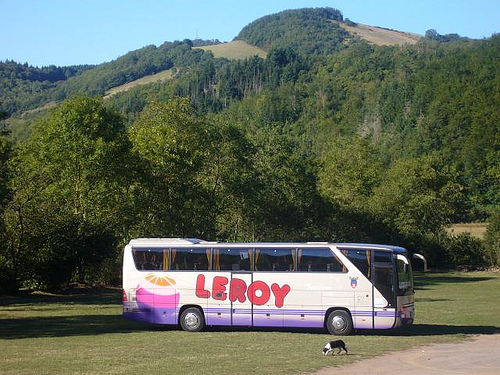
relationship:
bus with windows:
[122, 237, 427, 336] [296, 248, 348, 272]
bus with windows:
[122, 237, 427, 336] [252, 247, 296, 271]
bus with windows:
[122, 237, 427, 336] [211, 247, 251, 269]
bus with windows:
[122, 237, 427, 336] [167, 248, 209, 268]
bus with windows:
[122, 237, 427, 336] [132, 246, 169, 270]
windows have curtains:
[130, 237, 370, 282] [157, 248, 311, 273]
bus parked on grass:
[122, 237, 427, 336] [2, 265, 498, 374]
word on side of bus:
[192, 272, 294, 309] [107, 224, 413, 325]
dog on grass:
[312, 333, 355, 353] [0, 243, 499, 374]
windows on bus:
[283, 241, 347, 298] [105, 231, 437, 365]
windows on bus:
[133, 241, 260, 288] [105, 231, 437, 365]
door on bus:
[374, 253, 399, 327] [80, 136, 467, 373]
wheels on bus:
[326, 309, 353, 336] [121, 237, 424, 342]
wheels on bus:
[175, 304, 207, 331] [121, 237, 424, 342]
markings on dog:
[317, 345, 336, 351] [318, 340, 353, 359]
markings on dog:
[327, 341, 354, 351] [323, 337, 351, 354]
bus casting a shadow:
[107, 224, 413, 325] [27, 292, 77, 342]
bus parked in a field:
[107, 224, 413, 325] [44, 269, 367, 369]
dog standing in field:
[322, 339, 348, 356] [67, 281, 217, 372]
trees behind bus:
[0, 9, 498, 297] [122, 237, 427, 336]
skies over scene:
[44, 18, 154, 46] [12, 22, 407, 219]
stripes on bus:
[127, 302, 384, 330] [117, 226, 428, 339]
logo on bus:
[195, 274, 291, 308] [117, 226, 428, 339]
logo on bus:
[186, 274, 311, 308] [144, 223, 491, 348]